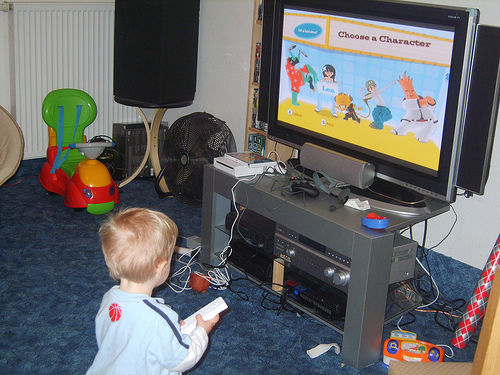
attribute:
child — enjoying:
[71, 197, 231, 373]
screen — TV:
[274, 10, 481, 200]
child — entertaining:
[21, 175, 249, 371]